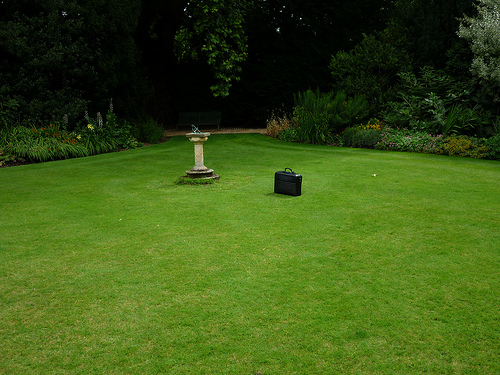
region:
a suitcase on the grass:
[242, 140, 323, 222]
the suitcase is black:
[234, 130, 316, 232]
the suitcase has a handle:
[275, 162, 296, 176]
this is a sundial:
[168, 91, 222, 186]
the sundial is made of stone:
[159, 98, 212, 176]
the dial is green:
[190, 120, 205, 137]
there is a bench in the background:
[162, 101, 235, 144]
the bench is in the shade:
[157, 100, 233, 127]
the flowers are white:
[60, 113, 97, 154]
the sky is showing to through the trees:
[237, 3, 314, 42]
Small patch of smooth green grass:
[214, 270, 244, 299]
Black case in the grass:
[276, 167, 303, 199]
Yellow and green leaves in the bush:
[443, 141, 471, 157]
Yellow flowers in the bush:
[372, 121, 379, 130]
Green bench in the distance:
[178, 112, 223, 127]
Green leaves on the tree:
[205, 12, 240, 66]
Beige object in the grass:
[187, 135, 209, 170]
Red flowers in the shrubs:
[52, 126, 61, 141]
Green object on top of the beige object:
[192, 123, 202, 133]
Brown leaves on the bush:
[268, 117, 284, 137]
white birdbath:
[165, 115, 223, 190]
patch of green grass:
[350, 290, 395, 335]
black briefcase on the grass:
[271, 161, 301, 201]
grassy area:
[100, 245, 290, 315]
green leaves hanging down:
[230, 25, 305, 105]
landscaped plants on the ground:
[295, 110, 480, 160]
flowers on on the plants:
[50, 100, 110, 150]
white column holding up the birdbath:
[170, 130, 230, 175]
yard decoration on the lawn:
[160, 115, 225, 180]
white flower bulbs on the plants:
[56, 111, 103, 151]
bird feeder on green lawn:
[174, 115, 220, 176]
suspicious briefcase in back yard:
[261, 163, 316, 201]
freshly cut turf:
[31, 231, 358, 330]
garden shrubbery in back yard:
[6, 107, 135, 154]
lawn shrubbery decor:
[280, 32, 490, 162]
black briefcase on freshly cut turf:
[260, 162, 317, 202]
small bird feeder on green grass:
[174, 122, 217, 192]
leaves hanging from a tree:
[173, 0, 265, 92]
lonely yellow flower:
[68, 120, 122, 143]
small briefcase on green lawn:
[263, 160, 310, 190]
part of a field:
[161, 199, 207, 289]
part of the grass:
[94, 100, 127, 263]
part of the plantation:
[405, 142, 444, 236]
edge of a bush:
[408, 103, 440, 148]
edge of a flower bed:
[73, 124, 99, 141]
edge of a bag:
[292, 170, 301, 201]